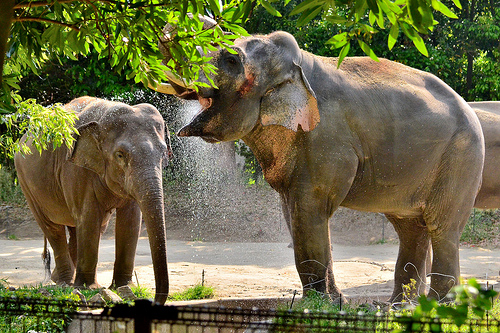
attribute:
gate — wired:
[0, 297, 498, 332]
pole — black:
[113, 297, 179, 332]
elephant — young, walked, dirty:
[15, 96, 171, 303]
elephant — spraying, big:
[123, 12, 486, 311]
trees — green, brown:
[0, 1, 247, 169]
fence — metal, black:
[2, 295, 500, 332]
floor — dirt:
[0, 232, 499, 313]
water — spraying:
[176, 98, 243, 238]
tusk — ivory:
[139, 60, 197, 98]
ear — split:
[259, 64, 324, 133]